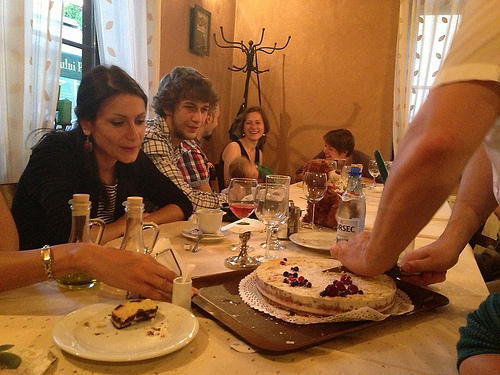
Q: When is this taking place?
A: Daytime.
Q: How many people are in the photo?
A: Eight.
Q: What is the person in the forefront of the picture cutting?
A: Cake.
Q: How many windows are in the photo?
A: Two.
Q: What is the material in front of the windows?
A: Curtains.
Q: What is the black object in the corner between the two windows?
A: Coat stand.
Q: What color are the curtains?
A: White sheer.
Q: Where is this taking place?
A: In a dining room.